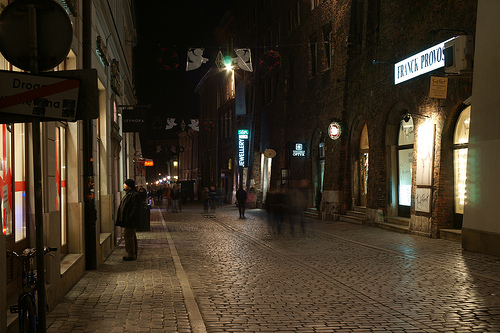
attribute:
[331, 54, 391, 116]
wall —  old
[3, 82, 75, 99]
line — red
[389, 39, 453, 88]
sign — lighted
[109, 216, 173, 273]
pants — tan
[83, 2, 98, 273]
pole —  straight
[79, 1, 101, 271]
pole — black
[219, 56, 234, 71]
light — on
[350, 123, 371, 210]
windows — U's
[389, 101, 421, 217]
windows — U's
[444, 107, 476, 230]
windows — U's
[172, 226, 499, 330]
floor — light brown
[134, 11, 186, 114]
sky — black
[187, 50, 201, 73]
angel — White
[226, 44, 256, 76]
angel — White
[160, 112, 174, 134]
angel — White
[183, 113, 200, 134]
angel — White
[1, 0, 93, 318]
sign — round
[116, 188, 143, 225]
jacket — big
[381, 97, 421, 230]
shape — arched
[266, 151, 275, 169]
light — on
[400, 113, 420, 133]
light — on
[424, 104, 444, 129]
light — on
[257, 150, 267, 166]
light — on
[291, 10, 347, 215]
wall —  old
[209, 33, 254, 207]
wall —  old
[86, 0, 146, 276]
wall —  old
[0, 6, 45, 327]
wall —  old